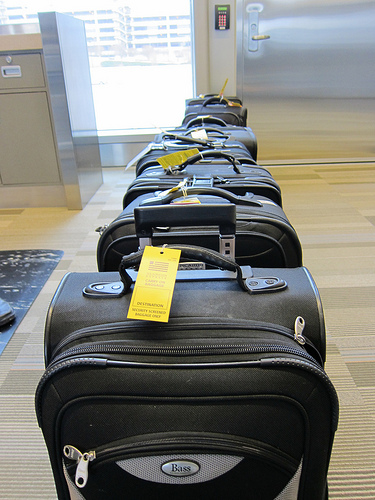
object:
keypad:
[213, 1, 232, 35]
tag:
[125, 243, 180, 327]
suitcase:
[85, 176, 311, 275]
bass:
[158, 455, 203, 475]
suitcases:
[30, 232, 349, 495]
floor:
[0, 158, 373, 500]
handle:
[246, 27, 272, 48]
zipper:
[52, 324, 323, 371]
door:
[232, 0, 373, 165]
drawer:
[0, 50, 48, 95]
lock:
[5, 50, 16, 65]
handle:
[125, 195, 240, 251]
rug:
[1, 246, 64, 355]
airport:
[0, 1, 374, 497]